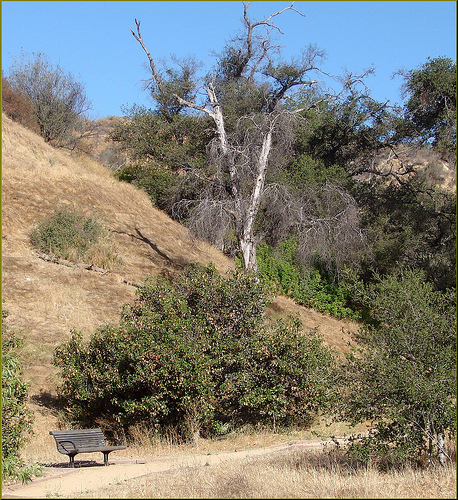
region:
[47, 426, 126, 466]
A bench along a walking path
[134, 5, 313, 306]
an old dead tree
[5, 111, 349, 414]
A very steep hill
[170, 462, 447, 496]
Dried out and sunburnt vegetation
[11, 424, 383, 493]
A dirt walking path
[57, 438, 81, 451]
A metal elbow rest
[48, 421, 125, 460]
A bench in the park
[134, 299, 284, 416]
Trees in the park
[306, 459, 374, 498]
Dry grass in the park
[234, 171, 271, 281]
A tree trunk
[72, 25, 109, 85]
Blue skies in the background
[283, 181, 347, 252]
Dry leaves on the tree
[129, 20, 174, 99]
Branch with no leaves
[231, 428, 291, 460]
A dirt track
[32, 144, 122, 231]
A slope in the background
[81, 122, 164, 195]
A valley in the background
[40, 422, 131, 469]
wooden bench on walkway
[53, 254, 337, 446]
green bush behind bench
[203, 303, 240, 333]
lavender flowers ingreen bush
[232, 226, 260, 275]
brown tree trunk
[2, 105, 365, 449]
dirt covered hillside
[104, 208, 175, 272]
shadow of tree on hillside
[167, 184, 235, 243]
bare, leafless tree branches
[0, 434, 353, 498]
dirt walk way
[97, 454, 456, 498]
yellowed grass on ground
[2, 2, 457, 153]
blue sky above hillside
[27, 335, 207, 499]
a brown wooden bench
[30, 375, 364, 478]
a bench on the side of a path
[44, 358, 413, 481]
a long narrow dirt path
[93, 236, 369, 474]
green shrubbery on a path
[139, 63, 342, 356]
a tall dead tree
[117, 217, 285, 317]
shaddow of dead tree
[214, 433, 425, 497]
a dead grassy field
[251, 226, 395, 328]
bright green shrubbery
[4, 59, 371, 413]
a steep mountain side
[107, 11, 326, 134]
more dead trees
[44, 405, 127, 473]
this is a bench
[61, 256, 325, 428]
this is a bushy tree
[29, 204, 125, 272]
this is a bushy tree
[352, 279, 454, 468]
this is a bushy tree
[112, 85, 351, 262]
this is a bushy tree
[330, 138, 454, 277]
this is a bushy tree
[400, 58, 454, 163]
this is a bushy tree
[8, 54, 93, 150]
this is a bushy tree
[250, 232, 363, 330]
this is a bushy tree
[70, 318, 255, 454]
this is a bushy tree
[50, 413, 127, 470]
A bench in the park.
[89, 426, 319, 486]
A walking trail in the forest.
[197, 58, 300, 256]
A tree with no leaves.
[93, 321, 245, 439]
A tree next to the bench.